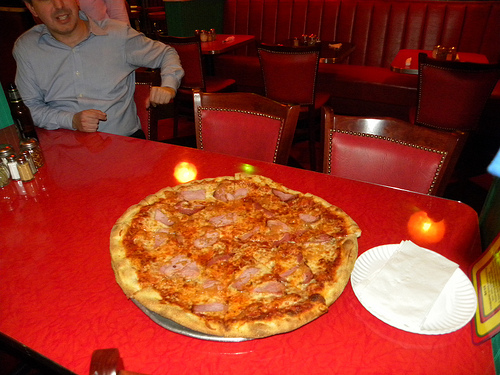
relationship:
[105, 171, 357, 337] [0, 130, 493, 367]
crust on table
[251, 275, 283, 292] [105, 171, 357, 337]
meat on crust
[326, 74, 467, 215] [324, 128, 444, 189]
chair with padding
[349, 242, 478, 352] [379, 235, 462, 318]
plate with napkins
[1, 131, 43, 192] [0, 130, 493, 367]
spices are on table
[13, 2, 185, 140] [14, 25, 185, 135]
man wearing a long sleeve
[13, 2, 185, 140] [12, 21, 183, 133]
man wearing a shirt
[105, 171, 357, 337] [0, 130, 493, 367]
crust on a table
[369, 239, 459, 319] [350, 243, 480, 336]
napkins are on a plate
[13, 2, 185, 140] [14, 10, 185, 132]
man has on long sleeve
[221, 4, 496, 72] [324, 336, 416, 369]
wall behind table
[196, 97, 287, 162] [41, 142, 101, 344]
chair near table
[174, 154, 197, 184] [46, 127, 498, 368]
light reflecting off table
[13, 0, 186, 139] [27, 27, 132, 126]
man wearing a shirt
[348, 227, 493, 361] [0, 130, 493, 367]
plate on table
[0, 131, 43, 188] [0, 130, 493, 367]
spices on table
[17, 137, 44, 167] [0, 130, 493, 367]
pepper on table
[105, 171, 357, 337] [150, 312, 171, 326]
crust on plate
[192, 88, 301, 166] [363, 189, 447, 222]
chair at table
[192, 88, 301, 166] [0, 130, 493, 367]
chair at table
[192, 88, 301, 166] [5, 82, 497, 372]
chair at table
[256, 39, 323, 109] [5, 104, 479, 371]
chair at table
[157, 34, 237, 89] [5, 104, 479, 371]
chair at table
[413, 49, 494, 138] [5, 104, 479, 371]
chair at table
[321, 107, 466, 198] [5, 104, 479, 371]
chair at table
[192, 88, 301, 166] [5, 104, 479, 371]
chair at table